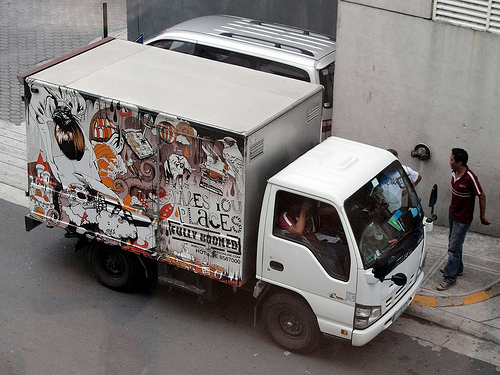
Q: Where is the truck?
A: Side of road.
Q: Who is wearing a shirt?
A: The man.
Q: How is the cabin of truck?
A: White.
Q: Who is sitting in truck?
A: The man.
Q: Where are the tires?
A: The truck.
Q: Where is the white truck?
A: Near the curb.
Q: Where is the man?
A: Standing outside the truck.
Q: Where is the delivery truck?
A: Next to the sidewalk.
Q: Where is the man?
A: Standing by delivery truck.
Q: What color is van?
A: White.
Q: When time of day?
A: Daytime.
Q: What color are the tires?
A: Black.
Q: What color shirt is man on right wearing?
A: Maroon.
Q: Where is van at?
A: On the road.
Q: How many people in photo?
A: 3.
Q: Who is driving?
A: Man.